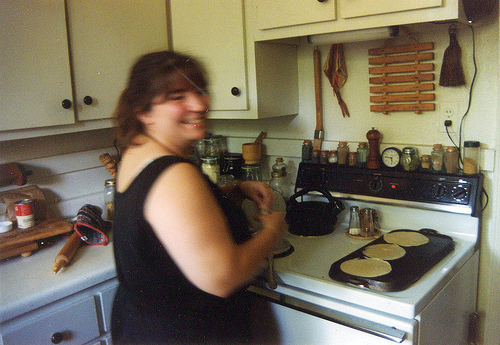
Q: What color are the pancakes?
A: Brown.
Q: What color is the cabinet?
A: White.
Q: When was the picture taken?
A: Morning.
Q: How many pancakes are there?
A: Three.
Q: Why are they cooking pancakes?
A: For breakfast.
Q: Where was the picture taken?
A: The kitchen.